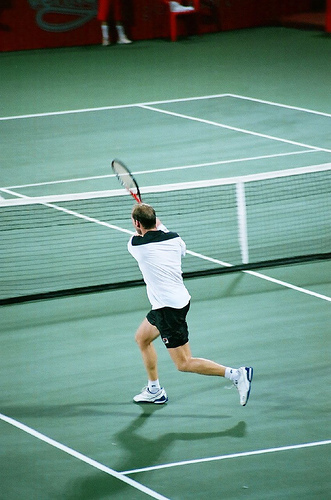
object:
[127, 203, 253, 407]
man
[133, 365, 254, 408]
shoes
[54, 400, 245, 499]
shadow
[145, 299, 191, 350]
shorts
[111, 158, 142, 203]
racket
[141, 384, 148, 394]
lace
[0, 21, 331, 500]
paint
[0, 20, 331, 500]
court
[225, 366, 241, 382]
sock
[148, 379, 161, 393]
sock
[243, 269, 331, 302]
line